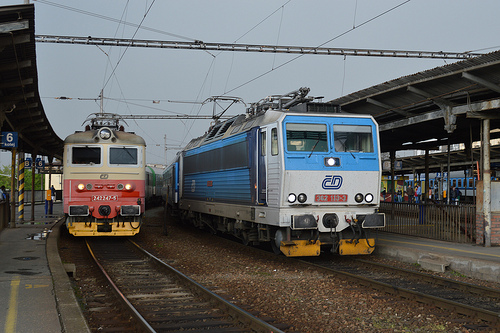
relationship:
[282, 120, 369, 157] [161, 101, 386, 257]
windshield on train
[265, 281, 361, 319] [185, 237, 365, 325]
gravel with rock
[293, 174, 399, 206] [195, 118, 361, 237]
headlights on train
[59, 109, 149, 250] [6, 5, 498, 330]
train in station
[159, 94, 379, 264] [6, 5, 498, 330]
train in station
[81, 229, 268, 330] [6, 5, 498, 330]
train tracks in station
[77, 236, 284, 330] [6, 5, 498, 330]
train tracks in station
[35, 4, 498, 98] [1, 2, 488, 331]
wires at train station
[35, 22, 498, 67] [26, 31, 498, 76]
wires at train station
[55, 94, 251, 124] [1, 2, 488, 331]
wires at train station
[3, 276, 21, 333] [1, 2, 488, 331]
barrier lines in train station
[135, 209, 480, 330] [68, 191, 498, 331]
dirt between train tracks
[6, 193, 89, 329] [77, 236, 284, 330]
sidewalk beside train tracks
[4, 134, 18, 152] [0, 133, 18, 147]
6 on sign